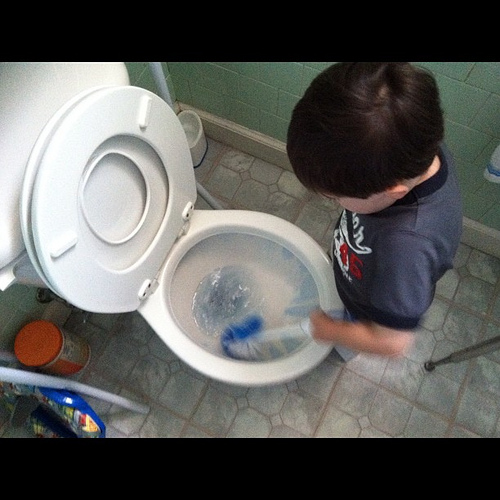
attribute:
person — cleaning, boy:
[281, 60, 460, 368]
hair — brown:
[288, 61, 444, 193]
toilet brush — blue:
[222, 309, 345, 360]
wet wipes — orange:
[14, 320, 89, 377]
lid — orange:
[15, 320, 62, 367]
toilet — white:
[0, 61, 346, 388]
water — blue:
[194, 263, 265, 338]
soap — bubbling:
[211, 270, 249, 311]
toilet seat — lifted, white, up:
[30, 85, 197, 313]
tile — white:
[2, 130, 500, 439]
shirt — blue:
[332, 142, 463, 329]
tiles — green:
[0, 62, 499, 369]